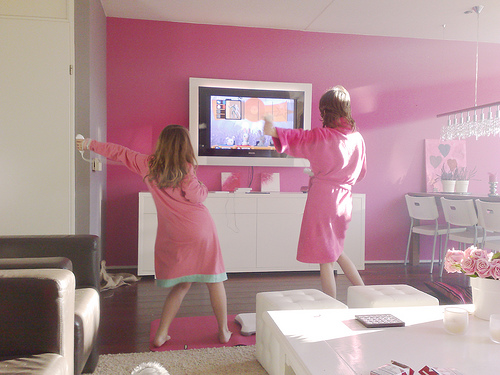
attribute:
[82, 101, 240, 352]
girl — playing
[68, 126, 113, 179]
controller — white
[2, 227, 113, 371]
chair — white, brown, leather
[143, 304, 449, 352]
rug — pink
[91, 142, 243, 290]
robe — pink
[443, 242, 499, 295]
flowers — pink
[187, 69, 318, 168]
tv — flat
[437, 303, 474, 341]
glass — clear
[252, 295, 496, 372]
table — white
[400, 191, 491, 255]
chair — white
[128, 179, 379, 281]
cabinet — white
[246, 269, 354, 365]
seat — brown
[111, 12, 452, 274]
wall — accented, pink